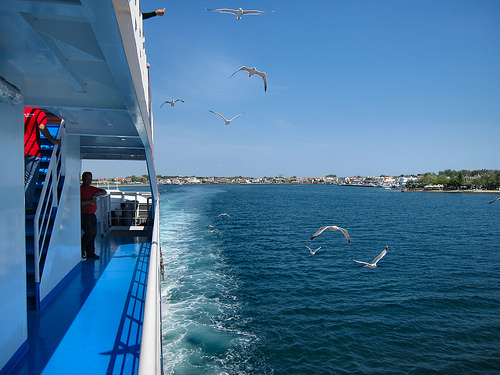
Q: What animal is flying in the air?
A: Birds.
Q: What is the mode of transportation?
A: Boat.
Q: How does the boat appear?
A: It is moving.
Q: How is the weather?
A: Clear and sunny.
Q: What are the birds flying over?
A: Water and boat.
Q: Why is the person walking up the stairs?
A: To get to top.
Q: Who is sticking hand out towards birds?
A: Person on top deck.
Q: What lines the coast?
A: Trees and buildings.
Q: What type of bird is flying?
A: Seagulls.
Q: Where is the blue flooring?
A: On deck and stairs.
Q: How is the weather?
A: Sunny.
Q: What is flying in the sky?
A: Birds.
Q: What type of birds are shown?
A: Seagulls.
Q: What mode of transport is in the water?
A: A large b oat.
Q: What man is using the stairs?
A: The left one.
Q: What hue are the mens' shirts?
A: Red.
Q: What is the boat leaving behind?
A: A water trail.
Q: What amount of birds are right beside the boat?
A: Three.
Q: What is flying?
A: Birds.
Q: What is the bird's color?
A: Gray.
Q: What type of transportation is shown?
A: Boat.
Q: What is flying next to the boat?
A: Seagulls.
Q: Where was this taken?
A: Ocean.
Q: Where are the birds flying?
A: In sky.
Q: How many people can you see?
A: Three.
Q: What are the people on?
A: A Boat.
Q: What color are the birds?
A: White, Black Grey.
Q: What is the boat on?
A: The water.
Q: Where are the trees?
A: Right side of photo.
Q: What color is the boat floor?
A: Blue.